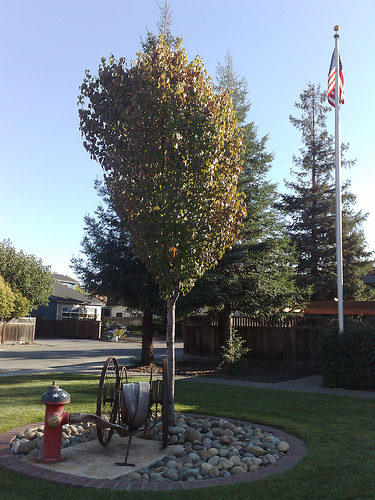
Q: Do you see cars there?
A: No, there are no cars.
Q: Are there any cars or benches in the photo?
A: No, there are no cars or benches.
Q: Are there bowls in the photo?
A: No, there are no bowls.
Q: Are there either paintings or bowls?
A: No, there are no bowls or paintings.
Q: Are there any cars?
A: No, there are no cars.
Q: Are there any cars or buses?
A: No, there are no cars or buses.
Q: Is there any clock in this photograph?
A: No, there are no clocks.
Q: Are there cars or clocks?
A: No, there are no clocks or cars.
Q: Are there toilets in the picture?
A: No, there are no toilets.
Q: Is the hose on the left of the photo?
A: Yes, the hose is on the left of the image.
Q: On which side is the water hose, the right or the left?
A: The water hose is on the left of the image.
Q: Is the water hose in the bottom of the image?
A: Yes, the water hose is in the bottom of the image.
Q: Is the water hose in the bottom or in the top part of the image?
A: The water hose is in the bottom of the image.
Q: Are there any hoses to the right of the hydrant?
A: Yes, there is a hose to the right of the hydrant.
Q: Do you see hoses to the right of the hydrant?
A: Yes, there is a hose to the right of the hydrant.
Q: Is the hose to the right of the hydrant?
A: Yes, the hose is to the right of the hydrant.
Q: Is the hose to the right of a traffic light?
A: No, the hose is to the right of the hydrant.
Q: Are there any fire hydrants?
A: Yes, there is a fire hydrant.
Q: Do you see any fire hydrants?
A: Yes, there is a fire hydrant.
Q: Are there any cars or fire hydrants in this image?
A: Yes, there is a fire hydrant.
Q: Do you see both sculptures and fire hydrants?
A: No, there is a fire hydrant but no sculptures.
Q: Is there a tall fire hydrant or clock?
A: Yes, there is a tall fire hydrant.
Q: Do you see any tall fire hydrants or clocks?
A: Yes, there is a tall fire hydrant.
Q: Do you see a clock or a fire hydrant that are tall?
A: Yes, the fire hydrant is tall.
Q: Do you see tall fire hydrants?
A: Yes, there is a tall fire hydrant.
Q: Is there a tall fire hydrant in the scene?
A: Yes, there is a tall fire hydrant.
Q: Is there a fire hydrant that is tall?
A: Yes, there is a fire hydrant that is tall.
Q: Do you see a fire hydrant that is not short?
A: Yes, there is a tall fire hydrant.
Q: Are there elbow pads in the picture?
A: No, there are no elbow pads.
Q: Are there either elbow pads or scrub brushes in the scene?
A: No, there are no elbow pads or scrub brushes.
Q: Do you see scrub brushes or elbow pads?
A: No, there are no elbow pads or scrub brushes.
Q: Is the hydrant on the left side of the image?
A: Yes, the hydrant is on the left of the image.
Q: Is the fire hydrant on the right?
A: No, the fire hydrant is on the left of the image.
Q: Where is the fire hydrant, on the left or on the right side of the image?
A: The fire hydrant is on the left of the image.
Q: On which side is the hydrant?
A: The hydrant is on the left of the image.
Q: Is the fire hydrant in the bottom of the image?
A: Yes, the fire hydrant is in the bottom of the image.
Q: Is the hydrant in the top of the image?
A: No, the hydrant is in the bottom of the image.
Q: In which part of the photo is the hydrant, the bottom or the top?
A: The hydrant is in the bottom of the image.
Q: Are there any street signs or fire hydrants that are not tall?
A: No, there is a fire hydrant but it is tall.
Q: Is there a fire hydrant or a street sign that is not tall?
A: No, there is a fire hydrant but it is tall.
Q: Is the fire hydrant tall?
A: Yes, the fire hydrant is tall.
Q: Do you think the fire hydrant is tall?
A: Yes, the fire hydrant is tall.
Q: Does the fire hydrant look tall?
A: Yes, the fire hydrant is tall.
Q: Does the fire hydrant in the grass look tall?
A: Yes, the hydrant is tall.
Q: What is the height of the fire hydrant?
A: The fire hydrant is tall.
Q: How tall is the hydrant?
A: The hydrant is tall.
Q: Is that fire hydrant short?
A: No, the fire hydrant is tall.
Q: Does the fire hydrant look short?
A: No, the fire hydrant is tall.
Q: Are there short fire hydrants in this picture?
A: No, there is a fire hydrant but it is tall.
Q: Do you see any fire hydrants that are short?
A: No, there is a fire hydrant but it is tall.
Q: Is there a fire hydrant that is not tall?
A: No, there is a fire hydrant but it is tall.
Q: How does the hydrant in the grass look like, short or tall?
A: The fire hydrant is tall.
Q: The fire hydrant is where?
A: The fire hydrant is in the grass.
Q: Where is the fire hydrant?
A: The fire hydrant is in the grass.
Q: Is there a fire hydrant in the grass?
A: Yes, there is a fire hydrant in the grass.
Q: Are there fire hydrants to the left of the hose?
A: Yes, there is a fire hydrant to the left of the hose.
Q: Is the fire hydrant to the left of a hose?
A: Yes, the fire hydrant is to the left of a hose.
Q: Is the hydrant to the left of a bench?
A: No, the hydrant is to the left of a hose.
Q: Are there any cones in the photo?
A: No, there are no cones.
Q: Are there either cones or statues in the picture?
A: No, there are no cones or statues.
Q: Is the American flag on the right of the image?
A: Yes, the American flag is on the right of the image.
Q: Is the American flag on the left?
A: No, the American flag is on the right of the image.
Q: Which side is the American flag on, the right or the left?
A: The American flag is on the right of the image.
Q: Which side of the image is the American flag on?
A: The American flag is on the right of the image.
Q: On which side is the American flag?
A: The American flag is on the right of the image.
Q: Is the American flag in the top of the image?
A: Yes, the American flag is in the top of the image.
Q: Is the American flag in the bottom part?
A: No, the American flag is in the top of the image.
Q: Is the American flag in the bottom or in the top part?
A: The American flag is in the top of the image.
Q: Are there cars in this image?
A: No, there are no cars.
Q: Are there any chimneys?
A: No, there are no chimneys.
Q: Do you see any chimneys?
A: No, there are no chimneys.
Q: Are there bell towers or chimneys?
A: No, there are no chimneys or bell towers.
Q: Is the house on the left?
A: Yes, the house is on the left of the image.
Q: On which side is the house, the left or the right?
A: The house is on the left of the image.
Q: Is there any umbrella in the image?
A: No, there are no umbrellas.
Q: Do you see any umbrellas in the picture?
A: No, there are no umbrellas.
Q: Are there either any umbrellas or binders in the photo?
A: No, there are no umbrellas or binders.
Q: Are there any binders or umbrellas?
A: No, there are no umbrellas or binders.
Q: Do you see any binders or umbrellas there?
A: No, there are no umbrellas or binders.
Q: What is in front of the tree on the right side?
A: The post is in front of the pine tree.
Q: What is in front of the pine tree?
A: The post is in front of the pine tree.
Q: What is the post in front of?
A: The post is in front of the pine.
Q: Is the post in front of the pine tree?
A: Yes, the post is in front of the pine tree.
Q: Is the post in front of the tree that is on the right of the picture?
A: Yes, the post is in front of the pine tree.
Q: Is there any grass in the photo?
A: Yes, there is grass.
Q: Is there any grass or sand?
A: Yes, there is grass.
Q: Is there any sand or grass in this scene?
A: Yes, there is grass.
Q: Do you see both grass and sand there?
A: No, there is grass but no sand.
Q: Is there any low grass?
A: Yes, there is low grass.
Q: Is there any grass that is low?
A: Yes, there is grass that is low.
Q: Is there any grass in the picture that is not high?
A: Yes, there is low grass.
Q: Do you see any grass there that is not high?
A: Yes, there is low grass.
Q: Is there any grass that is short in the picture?
A: Yes, there is short grass.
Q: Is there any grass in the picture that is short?
A: Yes, there is grass that is short.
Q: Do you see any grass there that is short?
A: Yes, there is grass that is short.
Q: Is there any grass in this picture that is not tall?
A: Yes, there is short grass.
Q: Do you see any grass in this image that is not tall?
A: Yes, there is short grass.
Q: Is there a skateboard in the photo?
A: No, there are no skateboards.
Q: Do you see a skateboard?
A: No, there are no skateboards.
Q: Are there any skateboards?
A: No, there are no skateboards.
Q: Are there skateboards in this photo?
A: No, there are no skateboards.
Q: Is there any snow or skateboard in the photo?
A: No, there are no skateboards or snow.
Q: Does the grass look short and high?
A: No, the grass is short but low.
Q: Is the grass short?
A: Yes, the grass is short.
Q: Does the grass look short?
A: Yes, the grass is short.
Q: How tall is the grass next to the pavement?
A: The grass is short.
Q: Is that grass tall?
A: No, the grass is short.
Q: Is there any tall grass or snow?
A: No, there is grass but it is short.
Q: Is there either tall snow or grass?
A: No, there is grass but it is short.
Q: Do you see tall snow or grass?
A: No, there is grass but it is short.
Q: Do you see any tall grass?
A: No, there is grass but it is short.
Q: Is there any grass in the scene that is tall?
A: No, there is grass but it is short.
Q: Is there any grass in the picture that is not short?
A: No, there is grass but it is short.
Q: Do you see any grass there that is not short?
A: No, there is grass but it is short.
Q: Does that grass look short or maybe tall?
A: The grass is short.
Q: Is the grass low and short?
A: Yes, the grass is low and short.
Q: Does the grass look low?
A: Yes, the grass is low.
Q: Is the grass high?
A: No, the grass is low.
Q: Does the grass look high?
A: No, the grass is low.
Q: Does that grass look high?
A: No, the grass is low.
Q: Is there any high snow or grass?
A: No, there is grass but it is low.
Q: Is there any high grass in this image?
A: No, there is grass but it is low.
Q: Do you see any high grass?
A: No, there is grass but it is low.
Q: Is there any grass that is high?
A: No, there is grass but it is low.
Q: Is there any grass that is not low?
A: No, there is grass but it is low.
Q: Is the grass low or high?
A: The grass is low.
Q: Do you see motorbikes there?
A: No, there are no motorbikes.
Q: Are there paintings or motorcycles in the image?
A: No, there are no motorcycles or paintings.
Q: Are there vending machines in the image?
A: No, there are no vending machines.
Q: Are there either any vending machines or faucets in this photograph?
A: No, there are no vending machines or faucets.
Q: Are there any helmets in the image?
A: No, there are no helmets.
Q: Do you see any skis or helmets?
A: No, there are no helmets or skis.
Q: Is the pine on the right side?
A: Yes, the pine is on the right of the image.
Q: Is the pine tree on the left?
A: No, the pine tree is on the right of the image.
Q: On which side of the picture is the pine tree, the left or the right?
A: The pine tree is on the right of the image.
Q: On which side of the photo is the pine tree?
A: The pine tree is on the right of the image.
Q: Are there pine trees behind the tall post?
A: Yes, there is a pine tree behind the post.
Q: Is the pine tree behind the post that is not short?
A: Yes, the pine tree is behind the post.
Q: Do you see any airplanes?
A: No, there are no airplanes.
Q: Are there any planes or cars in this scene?
A: No, there are no planes or cars.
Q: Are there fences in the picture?
A: Yes, there is a fence.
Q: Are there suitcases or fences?
A: Yes, there is a fence.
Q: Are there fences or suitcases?
A: Yes, there is a fence.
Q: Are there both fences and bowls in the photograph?
A: No, there is a fence but no bowls.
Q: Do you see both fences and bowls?
A: No, there is a fence but no bowls.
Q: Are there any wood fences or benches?
A: Yes, there is a wood fence.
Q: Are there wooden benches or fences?
A: Yes, there is a wood fence.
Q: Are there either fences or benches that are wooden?
A: Yes, the fence is wooden.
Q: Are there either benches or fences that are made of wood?
A: Yes, the fence is made of wood.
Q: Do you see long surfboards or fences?
A: Yes, there is a long fence.